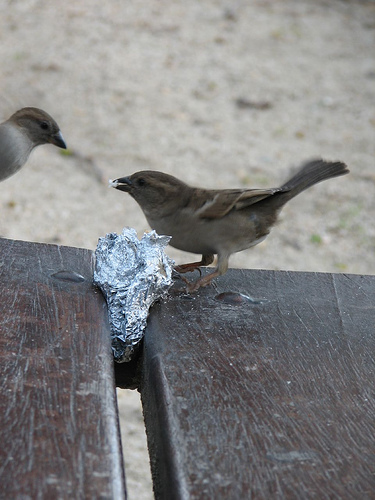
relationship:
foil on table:
[90, 231, 172, 367] [3, 233, 374, 498]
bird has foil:
[106, 155, 351, 296] [106, 179, 119, 191]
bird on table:
[106, 155, 351, 296] [3, 233, 374, 498]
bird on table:
[1, 106, 68, 180] [3, 233, 374, 498]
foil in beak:
[106, 179, 119, 191] [110, 177, 132, 192]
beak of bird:
[110, 177, 132, 192] [106, 155, 351, 296]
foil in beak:
[90, 231, 172, 367] [110, 177, 132, 192]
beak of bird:
[50, 132, 69, 150] [1, 106, 68, 180]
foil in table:
[90, 231, 172, 367] [3, 233, 374, 498]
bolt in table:
[209, 289, 253, 305] [3, 233, 374, 498]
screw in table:
[50, 269, 88, 283] [3, 233, 374, 498]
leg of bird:
[185, 252, 232, 299] [106, 155, 351, 296]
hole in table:
[100, 348, 186, 500] [3, 233, 374, 498]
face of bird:
[35, 116, 62, 148] [1, 106, 68, 180]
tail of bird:
[274, 155, 351, 204] [106, 155, 351, 296]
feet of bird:
[166, 262, 222, 296] [106, 155, 351, 296]